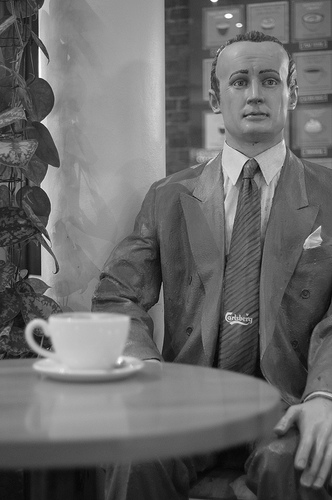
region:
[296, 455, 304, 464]
white plastic statue fingernail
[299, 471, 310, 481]
white plastic statue fingernail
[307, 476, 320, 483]
white plastic statue fingernail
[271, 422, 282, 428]
white plastic statue fingernail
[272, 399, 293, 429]
white plastic statue finger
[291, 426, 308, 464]
white plastic statue finger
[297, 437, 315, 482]
white plastic statue finger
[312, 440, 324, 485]
white plastic statue finger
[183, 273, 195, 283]
black plastic jacket button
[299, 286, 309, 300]
black plastic jacket button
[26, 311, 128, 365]
A cup on a small plate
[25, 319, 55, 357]
The handle on the small cup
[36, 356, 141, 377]
A small plate on the table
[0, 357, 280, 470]
A table below the small plate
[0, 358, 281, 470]
The table is circular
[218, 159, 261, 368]
A tie on the mannequin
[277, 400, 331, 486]
The left hand of the mannequin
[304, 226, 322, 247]
A napkin in the pocket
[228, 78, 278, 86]
The eyes of the mannequin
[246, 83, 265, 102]
The nose of the mannequin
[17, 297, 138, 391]
a cup on the table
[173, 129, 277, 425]
mannequin is wearing a tie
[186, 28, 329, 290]
Statue of a man dressed in a suit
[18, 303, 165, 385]
Mug and plate on the table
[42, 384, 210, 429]
Reflection of light on the table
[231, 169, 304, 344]
Tie on the statue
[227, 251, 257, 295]
The tie has stripes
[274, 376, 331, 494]
Hand on statues knee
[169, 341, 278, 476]
The table is circular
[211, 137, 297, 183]
Shirt has a collar on it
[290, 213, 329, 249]
Pocket has a paper in it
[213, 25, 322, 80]
Man is going bald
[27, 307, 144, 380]
a white coffee cup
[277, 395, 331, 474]
the hand of the man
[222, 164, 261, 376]
the tie of the man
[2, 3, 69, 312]
the leaves of the plant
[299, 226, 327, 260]
the handkerchief of the man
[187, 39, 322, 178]
a statue of a man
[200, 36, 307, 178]
the mans face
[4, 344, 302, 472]
the table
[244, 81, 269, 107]
the nose of the man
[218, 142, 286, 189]
the collar of the shirt